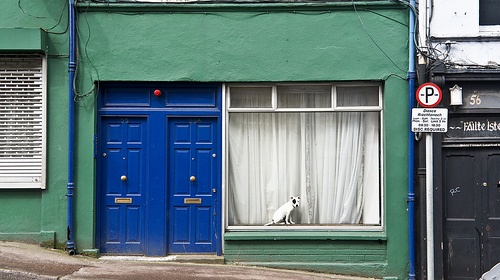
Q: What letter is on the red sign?
A: P.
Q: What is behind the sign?
A: Buildings.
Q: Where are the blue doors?
A: On the green building.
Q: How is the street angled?
A: Sloped right.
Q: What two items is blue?
A: The doors.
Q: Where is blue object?
A: The door.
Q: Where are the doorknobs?
A: On blue doors.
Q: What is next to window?
A: Blue doors.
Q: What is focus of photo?
A: Blue doors.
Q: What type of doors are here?
A: Blue doors.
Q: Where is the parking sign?
A: Right of blue doors.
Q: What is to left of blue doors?
A: Blue pipes.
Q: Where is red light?
A: Above doors.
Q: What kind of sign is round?
A: Parking.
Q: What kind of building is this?
A: Storefront.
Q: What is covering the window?
A: Curtains.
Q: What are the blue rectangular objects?
A: Doors.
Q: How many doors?
A: Three.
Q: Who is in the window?
A: A dog.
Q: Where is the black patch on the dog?
A: Right eye.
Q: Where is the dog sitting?
A: Window.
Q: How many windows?
A: One.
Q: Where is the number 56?
A: Above black door.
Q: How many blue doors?
A: Two.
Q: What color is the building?
A: Green.